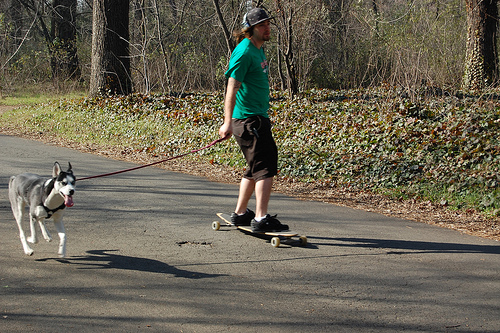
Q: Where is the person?
A: Park.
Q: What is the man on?
A: Skateboard.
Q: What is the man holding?
A: Leash.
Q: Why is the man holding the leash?
A: Walking the dog.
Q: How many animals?
A: 1.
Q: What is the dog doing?
A: Running.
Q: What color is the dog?
A: Black and white.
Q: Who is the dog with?
A: The man.